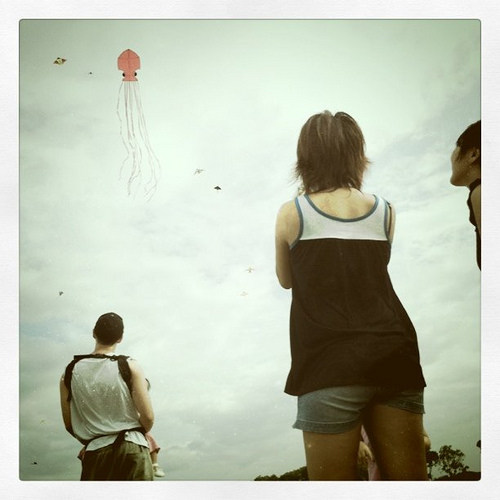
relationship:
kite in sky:
[116, 48, 162, 200] [18, 18, 482, 482]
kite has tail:
[116, 48, 162, 200] [119, 81, 162, 200]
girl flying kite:
[273, 108, 427, 480] [116, 48, 162, 200]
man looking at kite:
[58, 311, 157, 483] [116, 48, 162, 200]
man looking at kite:
[58, 311, 157, 483] [54, 56, 69, 66]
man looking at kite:
[58, 311, 157, 483] [196, 168, 206, 177]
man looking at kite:
[58, 311, 157, 483] [215, 185, 222, 191]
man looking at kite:
[58, 311, 157, 483] [59, 292, 66, 296]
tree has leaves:
[439, 445, 471, 477] [439, 444, 473, 478]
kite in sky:
[215, 185, 222, 191] [18, 18, 482, 482]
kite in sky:
[54, 56, 69, 66] [18, 18, 482, 482]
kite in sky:
[196, 168, 206, 177] [18, 18, 482, 482]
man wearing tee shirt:
[58, 311, 157, 483] [63, 353, 155, 452]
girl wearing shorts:
[273, 108, 427, 480] [292, 384, 426, 433]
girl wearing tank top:
[273, 108, 427, 480] [282, 189, 428, 397]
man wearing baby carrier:
[58, 311, 157, 483] [63, 352, 133, 451]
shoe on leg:
[152, 463, 164, 477] [143, 433, 164, 478]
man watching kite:
[58, 311, 157, 483] [116, 48, 162, 200]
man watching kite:
[58, 311, 157, 483] [54, 56, 69, 66]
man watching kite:
[58, 311, 157, 483] [196, 168, 206, 177]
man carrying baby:
[58, 311, 157, 483] [141, 377, 164, 475]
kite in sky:
[59, 292, 66, 296] [18, 18, 482, 482]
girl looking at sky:
[273, 108, 427, 480] [18, 18, 482, 482]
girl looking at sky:
[449, 118, 483, 272] [18, 18, 482, 482]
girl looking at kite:
[273, 108, 427, 480] [116, 48, 162, 200]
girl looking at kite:
[449, 118, 483, 272] [116, 48, 162, 200]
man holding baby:
[58, 311, 157, 483] [141, 377, 164, 475]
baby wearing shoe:
[141, 377, 164, 475] [152, 463, 164, 477]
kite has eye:
[116, 48, 162, 200] [120, 69, 129, 81]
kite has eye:
[116, 48, 162, 200] [134, 69, 140, 79]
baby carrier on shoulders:
[63, 352, 133, 451] [57, 356, 142, 394]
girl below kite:
[273, 108, 427, 480] [116, 48, 162, 200]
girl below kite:
[449, 118, 483, 272] [116, 48, 162, 200]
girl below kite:
[273, 108, 427, 480] [196, 168, 206, 177]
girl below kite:
[273, 108, 427, 480] [215, 185, 222, 191]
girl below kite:
[449, 118, 483, 272] [196, 168, 206, 177]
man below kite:
[58, 311, 157, 483] [54, 56, 69, 66]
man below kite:
[58, 311, 157, 483] [116, 48, 162, 200]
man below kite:
[58, 311, 157, 483] [196, 168, 206, 177]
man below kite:
[58, 311, 157, 483] [215, 185, 222, 191]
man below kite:
[58, 311, 157, 483] [59, 292, 66, 296]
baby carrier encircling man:
[63, 352, 133, 451] [58, 311, 157, 483]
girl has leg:
[273, 108, 427, 480] [296, 384, 376, 481]